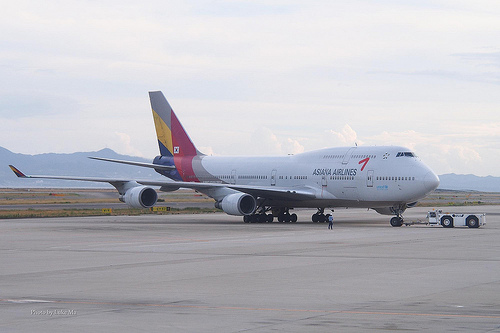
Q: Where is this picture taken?
A: At an airport.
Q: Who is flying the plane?
A: A man or woman.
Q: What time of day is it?
A: Daytime.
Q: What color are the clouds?
A: White.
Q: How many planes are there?
A: One.